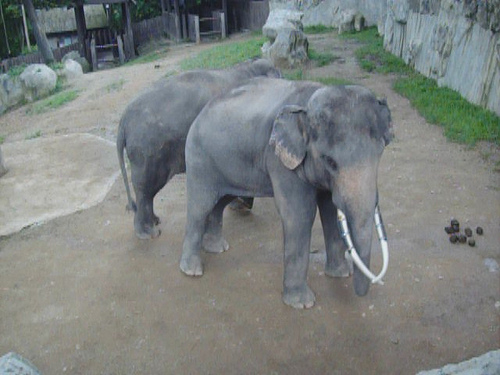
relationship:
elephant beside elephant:
[178, 85, 398, 305] [117, 55, 279, 238]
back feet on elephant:
[131, 222, 162, 243] [117, 55, 279, 238]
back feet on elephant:
[198, 232, 231, 257] [178, 85, 398, 305]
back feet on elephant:
[176, 244, 206, 279] [178, 85, 398, 305]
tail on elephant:
[105, 120, 137, 215] [178, 48, 433, 329]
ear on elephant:
[267, 104, 305, 171] [178, 85, 398, 305]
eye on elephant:
[325, 157, 337, 170] [178, 85, 398, 305]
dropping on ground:
[444, 219, 484, 245] [0, 26, 498, 370]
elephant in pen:
[178, 75, 392, 310] [1, 0, 499, 373]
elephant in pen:
[178, 85, 398, 305] [1, 0, 499, 373]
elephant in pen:
[117, 55, 279, 238] [1, 0, 499, 373]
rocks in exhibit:
[253, 14, 333, 74] [2, 0, 499, 370]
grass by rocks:
[437, 99, 467, 124] [259, 0, 499, 110]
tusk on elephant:
[369, 200, 387, 285] [178, 85, 398, 305]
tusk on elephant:
[335, 202, 386, 284] [178, 85, 398, 305]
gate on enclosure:
[185, 7, 239, 45] [3, 2, 498, 374]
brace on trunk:
[331, 210, 358, 259] [332, 150, 378, 297]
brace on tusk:
[370, 207, 388, 243] [372, 196, 390, 282]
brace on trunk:
[334, 210, 356, 251] [332, 150, 378, 297]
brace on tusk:
[370, 207, 388, 243] [369, 204, 388, 285]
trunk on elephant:
[332, 150, 378, 297] [156, 79, 436, 311]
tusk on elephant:
[369, 204, 388, 285] [156, 79, 436, 311]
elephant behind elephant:
[114, 59, 278, 240] [178, 85, 398, 305]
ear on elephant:
[265, 90, 314, 170] [178, 85, 398, 305]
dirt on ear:
[269, 132, 300, 169] [265, 90, 314, 170]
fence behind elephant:
[0, 14, 182, 69] [178, 85, 398, 305]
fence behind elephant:
[0, 14, 182, 69] [117, 55, 279, 238]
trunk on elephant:
[332, 150, 378, 297] [178, 85, 398, 305]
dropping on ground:
[444, 213, 484, 246] [0, 26, 498, 370]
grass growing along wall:
[15, 24, 499, 146] [2, 1, 499, 115]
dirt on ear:
[272, 138, 296, 169] [259, 93, 330, 187]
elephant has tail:
[117, 55, 279, 238] [113, 150, 133, 212]